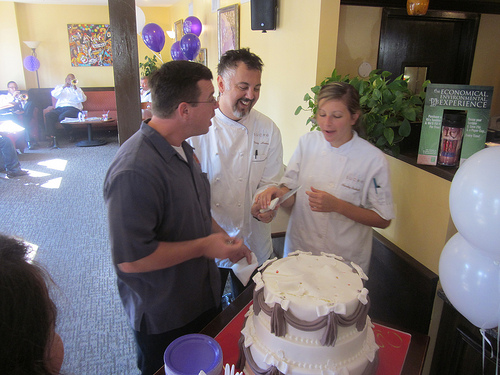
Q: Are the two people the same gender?
A: No, they are both male and female.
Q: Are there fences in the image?
A: No, there are no fences.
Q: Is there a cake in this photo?
A: Yes, there is a cake.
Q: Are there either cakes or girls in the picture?
A: Yes, there is a cake.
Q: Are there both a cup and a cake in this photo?
A: No, there is a cake but no cups.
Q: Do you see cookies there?
A: No, there are no cookies.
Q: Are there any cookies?
A: No, there are no cookies.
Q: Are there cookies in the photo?
A: No, there are no cookies.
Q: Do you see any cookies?
A: No, there are no cookies.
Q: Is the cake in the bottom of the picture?
A: Yes, the cake is in the bottom of the image.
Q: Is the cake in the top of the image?
A: No, the cake is in the bottom of the image.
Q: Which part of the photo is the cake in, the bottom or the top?
A: The cake is in the bottom of the image.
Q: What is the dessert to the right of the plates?
A: The dessert is a cake.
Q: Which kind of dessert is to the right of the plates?
A: The dessert is a cake.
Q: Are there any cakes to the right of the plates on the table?
A: Yes, there is a cake to the right of the plates.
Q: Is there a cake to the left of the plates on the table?
A: No, the cake is to the right of the plates.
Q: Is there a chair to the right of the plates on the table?
A: No, there is a cake to the right of the plates.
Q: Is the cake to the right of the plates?
A: Yes, the cake is to the right of the plates.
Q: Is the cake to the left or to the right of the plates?
A: The cake is to the right of the plates.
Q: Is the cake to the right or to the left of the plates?
A: The cake is to the right of the plates.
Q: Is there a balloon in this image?
A: Yes, there is a balloon.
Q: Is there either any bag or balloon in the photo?
A: Yes, there is a balloon.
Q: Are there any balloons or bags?
A: Yes, there is a balloon.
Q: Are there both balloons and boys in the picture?
A: No, there is a balloon but no boys.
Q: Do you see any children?
A: No, there are no children.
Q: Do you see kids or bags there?
A: No, there are no kids or bags.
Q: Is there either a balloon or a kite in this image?
A: Yes, there is a balloon.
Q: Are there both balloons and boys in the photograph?
A: No, there is a balloon but no boys.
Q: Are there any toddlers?
A: No, there are no toddlers.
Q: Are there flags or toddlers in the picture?
A: No, there are no toddlers or flags.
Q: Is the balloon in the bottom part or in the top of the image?
A: The balloon is in the top of the image.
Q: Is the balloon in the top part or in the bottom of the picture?
A: The balloon is in the top of the image.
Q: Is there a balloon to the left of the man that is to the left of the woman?
A: Yes, there is a balloon to the left of the man.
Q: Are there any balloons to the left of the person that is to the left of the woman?
A: Yes, there is a balloon to the left of the man.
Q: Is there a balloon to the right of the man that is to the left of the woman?
A: No, the balloon is to the left of the man.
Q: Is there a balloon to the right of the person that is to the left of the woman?
A: No, the balloon is to the left of the man.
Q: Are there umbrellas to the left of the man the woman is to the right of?
A: No, there is a balloon to the left of the man.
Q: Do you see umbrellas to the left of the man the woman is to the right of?
A: No, there is a balloon to the left of the man.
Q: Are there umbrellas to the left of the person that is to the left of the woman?
A: No, there is a balloon to the left of the man.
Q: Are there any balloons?
A: Yes, there is a balloon.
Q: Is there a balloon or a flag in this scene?
A: Yes, there is a balloon.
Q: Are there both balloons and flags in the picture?
A: No, there is a balloon but no flags.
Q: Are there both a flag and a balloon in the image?
A: No, there is a balloon but no flags.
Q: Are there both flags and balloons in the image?
A: No, there is a balloon but no flags.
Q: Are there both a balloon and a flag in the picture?
A: No, there is a balloon but no flags.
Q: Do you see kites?
A: No, there are no kites.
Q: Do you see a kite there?
A: No, there are no kites.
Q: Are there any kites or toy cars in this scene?
A: No, there are no kites or toy cars.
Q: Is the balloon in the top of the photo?
A: Yes, the balloon is in the top of the image.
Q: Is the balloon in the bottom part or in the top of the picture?
A: The balloon is in the top of the image.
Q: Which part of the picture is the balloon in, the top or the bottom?
A: The balloon is in the top of the image.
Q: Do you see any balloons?
A: Yes, there is a balloon.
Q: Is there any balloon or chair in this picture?
A: Yes, there is a balloon.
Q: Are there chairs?
A: No, there are no chairs.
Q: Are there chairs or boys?
A: No, there are no chairs or boys.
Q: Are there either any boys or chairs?
A: No, there are no chairs or boys.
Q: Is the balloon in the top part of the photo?
A: Yes, the balloon is in the top of the image.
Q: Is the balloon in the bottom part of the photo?
A: No, the balloon is in the top of the image.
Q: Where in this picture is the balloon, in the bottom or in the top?
A: The balloon is in the top of the image.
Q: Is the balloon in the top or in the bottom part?
A: The balloon is in the top of the image.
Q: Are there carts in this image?
A: No, there are no carts.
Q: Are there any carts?
A: No, there are no carts.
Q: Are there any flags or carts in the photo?
A: No, there are no carts or flags.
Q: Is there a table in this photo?
A: Yes, there is a table.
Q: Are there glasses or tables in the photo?
A: Yes, there is a table.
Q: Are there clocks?
A: No, there are no clocks.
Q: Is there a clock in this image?
A: No, there are no clocks.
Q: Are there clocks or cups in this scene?
A: No, there are no clocks or cups.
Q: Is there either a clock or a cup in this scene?
A: No, there are no clocks or cups.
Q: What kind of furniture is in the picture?
A: The furniture is a table.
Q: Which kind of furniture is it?
A: The piece of furniture is a table.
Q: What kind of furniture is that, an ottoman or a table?
A: This is a table.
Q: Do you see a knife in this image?
A: Yes, there is a knife.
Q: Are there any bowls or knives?
A: Yes, there is a knife.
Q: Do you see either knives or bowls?
A: Yes, there is a knife.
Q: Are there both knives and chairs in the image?
A: No, there is a knife but no chairs.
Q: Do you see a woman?
A: Yes, there is a woman.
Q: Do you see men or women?
A: Yes, there is a woman.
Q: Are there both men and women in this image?
A: Yes, there are both a woman and a man.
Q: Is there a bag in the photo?
A: No, there are no bags.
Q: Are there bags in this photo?
A: No, there are no bags.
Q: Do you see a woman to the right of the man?
A: Yes, there is a woman to the right of the man.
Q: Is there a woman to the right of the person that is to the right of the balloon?
A: Yes, there is a woman to the right of the man.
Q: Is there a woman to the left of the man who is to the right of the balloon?
A: No, the woman is to the right of the man.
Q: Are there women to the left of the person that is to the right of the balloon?
A: No, the woman is to the right of the man.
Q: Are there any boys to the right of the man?
A: No, there is a woman to the right of the man.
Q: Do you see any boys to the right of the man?
A: No, there is a woman to the right of the man.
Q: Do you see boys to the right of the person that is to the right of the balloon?
A: No, there is a woman to the right of the man.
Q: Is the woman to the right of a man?
A: Yes, the woman is to the right of a man.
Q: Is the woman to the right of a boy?
A: No, the woman is to the right of a man.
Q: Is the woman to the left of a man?
A: No, the woman is to the right of a man.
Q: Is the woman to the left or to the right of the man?
A: The woman is to the right of the man.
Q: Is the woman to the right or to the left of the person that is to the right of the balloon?
A: The woman is to the right of the man.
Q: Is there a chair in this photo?
A: No, there are no chairs.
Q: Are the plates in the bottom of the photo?
A: Yes, the plates are in the bottom of the image.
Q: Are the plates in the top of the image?
A: No, the plates are in the bottom of the image.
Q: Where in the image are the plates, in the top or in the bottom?
A: The plates are in the bottom of the image.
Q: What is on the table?
A: The plates are on the table.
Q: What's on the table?
A: The plates are on the table.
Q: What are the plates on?
A: The plates are on the table.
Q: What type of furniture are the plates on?
A: The plates are on the table.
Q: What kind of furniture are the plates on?
A: The plates are on the table.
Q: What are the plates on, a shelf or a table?
A: The plates are on a table.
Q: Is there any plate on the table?
A: Yes, there are plates on the table.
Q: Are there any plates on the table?
A: Yes, there are plates on the table.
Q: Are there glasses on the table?
A: No, there are plates on the table.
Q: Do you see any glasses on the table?
A: No, there are plates on the table.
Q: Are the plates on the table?
A: Yes, the plates are on the table.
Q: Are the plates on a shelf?
A: No, the plates are on the table.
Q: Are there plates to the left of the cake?
A: Yes, there are plates to the left of the cake.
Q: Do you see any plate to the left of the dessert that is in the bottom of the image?
A: Yes, there are plates to the left of the cake.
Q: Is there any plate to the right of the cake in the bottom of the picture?
A: No, the plates are to the left of the cake.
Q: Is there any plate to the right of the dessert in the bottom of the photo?
A: No, the plates are to the left of the cake.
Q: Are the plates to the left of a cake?
A: Yes, the plates are to the left of a cake.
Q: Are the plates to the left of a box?
A: No, the plates are to the left of a cake.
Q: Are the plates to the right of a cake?
A: No, the plates are to the left of a cake.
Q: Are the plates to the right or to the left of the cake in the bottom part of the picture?
A: The plates are to the left of the cake.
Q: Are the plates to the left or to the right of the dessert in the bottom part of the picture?
A: The plates are to the left of the cake.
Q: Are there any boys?
A: No, there are no boys.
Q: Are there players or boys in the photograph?
A: No, there are no boys or players.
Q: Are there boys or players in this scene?
A: No, there are no boys or players.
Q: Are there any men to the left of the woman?
A: Yes, there is a man to the left of the woman.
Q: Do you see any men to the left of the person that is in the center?
A: Yes, there is a man to the left of the woman.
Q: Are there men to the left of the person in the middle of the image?
A: Yes, there is a man to the left of the woman.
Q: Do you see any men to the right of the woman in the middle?
A: No, the man is to the left of the woman.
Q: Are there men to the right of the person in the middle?
A: No, the man is to the left of the woman.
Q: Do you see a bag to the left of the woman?
A: No, there is a man to the left of the woman.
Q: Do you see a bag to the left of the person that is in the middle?
A: No, there is a man to the left of the woman.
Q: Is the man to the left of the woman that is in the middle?
A: Yes, the man is to the left of the woman.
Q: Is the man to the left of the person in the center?
A: Yes, the man is to the left of the woman.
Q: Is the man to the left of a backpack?
A: No, the man is to the left of the woman.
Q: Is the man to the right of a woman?
A: No, the man is to the left of a woman.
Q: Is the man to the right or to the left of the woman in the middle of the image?
A: The man is to the left of the woman.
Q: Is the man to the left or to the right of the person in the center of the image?
A: The man is to the left of the woman.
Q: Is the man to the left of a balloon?
A: No, the man is to the right of a balloon.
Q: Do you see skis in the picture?
A: No, there are no skis.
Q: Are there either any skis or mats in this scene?
A: No, there are no skis or mats.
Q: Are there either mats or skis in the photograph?
A: No, there are no skis or mats.